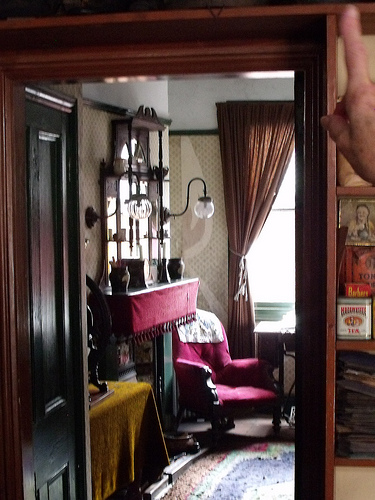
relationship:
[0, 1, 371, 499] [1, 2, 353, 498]
room has doorway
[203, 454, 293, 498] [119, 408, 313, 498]
light on surface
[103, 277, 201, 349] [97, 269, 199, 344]
cloth on mantlepiece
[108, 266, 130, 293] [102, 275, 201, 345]
vases on mantlepiece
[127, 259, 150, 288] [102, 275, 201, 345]
clock on mantlepiece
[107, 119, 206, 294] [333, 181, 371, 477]
antique containers on shelf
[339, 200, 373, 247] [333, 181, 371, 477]
photograph on shelf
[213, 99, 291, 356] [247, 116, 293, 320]
curtain on window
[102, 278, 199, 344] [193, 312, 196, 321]
cloth with tassel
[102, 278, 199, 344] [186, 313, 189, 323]
cloth with tassel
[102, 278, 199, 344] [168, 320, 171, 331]
cloth with tassel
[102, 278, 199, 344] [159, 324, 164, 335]
cloth with tassel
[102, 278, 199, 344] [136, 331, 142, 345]
cloth with tassel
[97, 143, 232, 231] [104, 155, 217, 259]
lights with poles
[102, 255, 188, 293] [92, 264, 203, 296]
vases on top